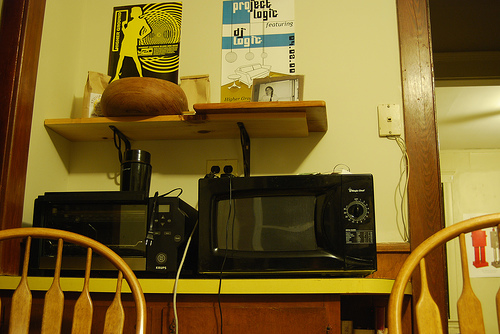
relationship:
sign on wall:
[221, 1, 294, 105] [66, 1, 411, 247]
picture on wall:
[107, 1, 182, 87] [66, 1, 411, 247]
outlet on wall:
[206, 159, 238, 178] [66, 1, 411, 247]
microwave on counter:
[197, 174, 377, 277] [0, 275, 413, 296]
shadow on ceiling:
[436, 109, 500, 127] [435, 86, 500, 151]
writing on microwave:
[344, 189, 373, 245] [197, 174, 377, 277]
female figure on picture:
[110, 6, 153, 82] [107, 1, 182, 87]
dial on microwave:
[349, 202, 364, 217] [197, 174, 377, 277]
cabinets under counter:
[0, 293, 340, 333] [0, 275, 413, 296]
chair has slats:
[0, 227, 148, 334] [10, 236, 126, 333]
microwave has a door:
[197, 174, 377, 277] [197, 173, 344, 273]